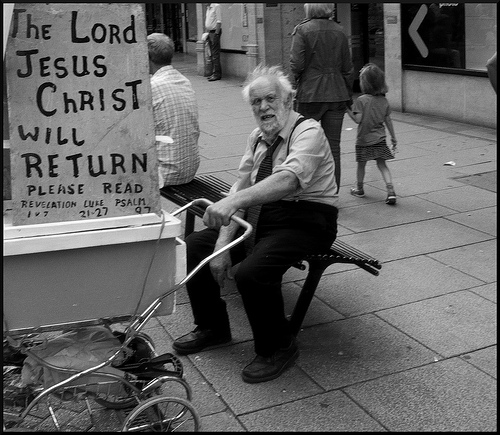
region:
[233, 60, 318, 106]
The man's hair is white.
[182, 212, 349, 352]
His pants are black.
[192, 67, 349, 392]
The man is sitting down.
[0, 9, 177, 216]
The sign has lettering.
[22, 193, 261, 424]
The man is holding a cart.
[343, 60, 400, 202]
The girl is young.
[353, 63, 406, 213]
The girl is walking.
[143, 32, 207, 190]
The man is sitting.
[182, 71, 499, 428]
The sidewalk is blocks.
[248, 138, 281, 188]
The man is wearing a tie.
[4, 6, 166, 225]
Jesus Christ saying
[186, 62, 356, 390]
Man sitting on bench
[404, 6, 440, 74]
Arrow pointing to the left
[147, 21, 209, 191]
Man looking away from the camera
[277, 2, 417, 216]
Woman and child holding hands.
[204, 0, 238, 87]
Person standing against the wall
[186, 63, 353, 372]
Man has white shirt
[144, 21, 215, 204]
Man wearing checkered shirt.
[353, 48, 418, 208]
Little girl wearing a skirt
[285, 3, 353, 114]
Woman with short hair wearing a jacket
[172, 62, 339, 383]
the man sitting on the bench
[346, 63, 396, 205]
the child walking on the sidewalk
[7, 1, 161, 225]
the sign next to the man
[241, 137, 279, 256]
the tie around the man's neck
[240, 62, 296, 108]
the hair on the man's head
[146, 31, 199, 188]
the man sitting at the edge of the bench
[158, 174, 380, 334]
the bench on the sidewalk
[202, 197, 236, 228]
the man's left hand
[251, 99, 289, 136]
the facial hair on the man's face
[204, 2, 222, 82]
the man standing in front of the building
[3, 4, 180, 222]
cardboard sign on cart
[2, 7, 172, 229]
black letters on sign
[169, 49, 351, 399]
man is holding the cart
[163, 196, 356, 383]
man's pants are black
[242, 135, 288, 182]
man is wearing a tie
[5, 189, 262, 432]
cart's handle is silver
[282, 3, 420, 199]
woman holding little girl's hand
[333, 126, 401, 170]
little girl wearing a skirt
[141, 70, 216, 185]
man's shirt is plaid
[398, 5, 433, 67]
arrow on the window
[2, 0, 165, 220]
a large black and white sign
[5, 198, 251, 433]
part of a baby carriage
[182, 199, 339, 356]
part of a man's black pants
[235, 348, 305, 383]
the shoe of a man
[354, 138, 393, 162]
a girl's skirt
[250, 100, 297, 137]
a man's white beard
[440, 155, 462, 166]
a piece of trash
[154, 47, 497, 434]
part of a sidewalk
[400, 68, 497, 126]
part of a brick building